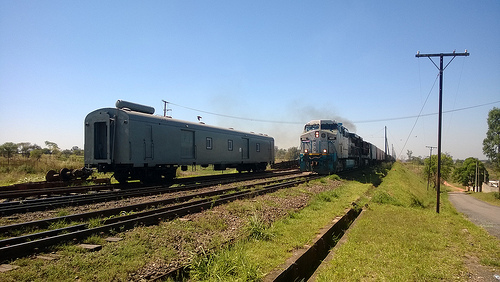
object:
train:
[296, 110, 403, 171]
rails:
[1, 135, 331, 256]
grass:
[1, 166, 321, 234]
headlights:
[302, 131, 333, 154]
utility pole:
[433, 49, 443, 213]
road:
[436, 171, 499, 240]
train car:
[83, 99, 280, 188]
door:
[94, 122, 109, 160]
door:
[181, 130, 199, 160]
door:
[242, 137, 252, 159]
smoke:
[208, 97, 361, 135]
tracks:
[2, 152, 318, 252]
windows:
[203, 137, 218, 150]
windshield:
[303, 118, 339, 131]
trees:
[480, 105, 500, 193]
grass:
[0, 150, 500, 281]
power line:
[393, 36, 473, 159]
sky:
[1, 1, 500, 160]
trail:
[436, 178, 468, 192]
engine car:
[301, 113, 358, 174]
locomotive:
[79, 98, 279, 175]